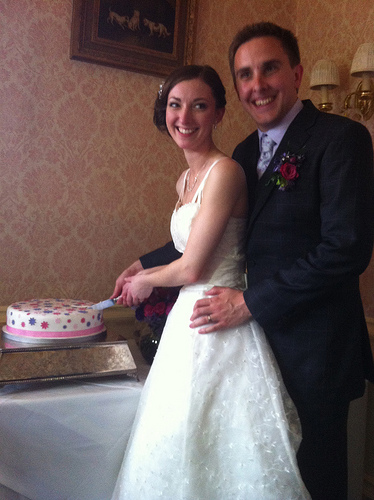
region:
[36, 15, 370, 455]
The couple look very happy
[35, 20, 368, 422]
This is a wedding photo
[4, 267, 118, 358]
The wedding cake is not very big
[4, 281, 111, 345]
The wedding cake has colored stars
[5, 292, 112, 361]
The wedding cake has white frosting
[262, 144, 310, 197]
The man has a rose in his button hole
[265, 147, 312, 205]
The rose is a red one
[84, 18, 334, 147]
The couple is smiling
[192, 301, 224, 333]
Man is wearing his wedding band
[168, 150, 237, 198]
The bride is wearing a necklace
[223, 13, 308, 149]
The man is smiling.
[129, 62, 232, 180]
The woman is smiling.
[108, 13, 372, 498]
The man is standing behind the woman.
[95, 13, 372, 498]
The man is wearing a ring on his left hand.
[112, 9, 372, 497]
The woman is wearing a wedding dress.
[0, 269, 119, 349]
The cake is pink, white and purple.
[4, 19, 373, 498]
The couple are posing.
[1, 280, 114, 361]
The cake is round.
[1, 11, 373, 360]
The couple are cutting the cake.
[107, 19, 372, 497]
The man is wearing a suit.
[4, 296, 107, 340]
frosted cake with pink and purple decorations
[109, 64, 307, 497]
woman wearing a white dress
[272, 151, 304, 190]
floral boutonniere on the man's jacket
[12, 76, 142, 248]
patterned wallpaper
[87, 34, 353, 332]
man and woman cutting a cake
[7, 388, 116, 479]
white tablecloth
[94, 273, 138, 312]
man and woman holding a knife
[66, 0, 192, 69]
framed artwork on the wall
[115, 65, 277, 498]
woman wearing a necklace and a wedding dress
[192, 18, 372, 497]
man wearing a suit and tie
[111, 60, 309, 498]
Woman wearing a white dress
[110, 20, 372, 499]
Man wearing a suit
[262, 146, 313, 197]
Roses on man's shirt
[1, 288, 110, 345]
Cake on a tray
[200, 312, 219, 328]
Ring on man's finger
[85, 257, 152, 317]
Knife in woman and man's hand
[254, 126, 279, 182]
Tie around man's neck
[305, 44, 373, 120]
Lamp on the wall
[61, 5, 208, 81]
Picture hanging on the wall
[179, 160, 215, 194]
Necklace on woman's neck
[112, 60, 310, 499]
a bride in a wedding dress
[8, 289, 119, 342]
a cake being cut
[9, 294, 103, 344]
a muli-colored cake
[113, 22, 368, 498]
a bride and a groom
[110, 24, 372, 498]
a married couple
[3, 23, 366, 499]
a wedding reception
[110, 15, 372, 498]
a man and woman smiling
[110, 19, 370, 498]
a couple standing together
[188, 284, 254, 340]
a hand with a wedding ring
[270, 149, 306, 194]
a corsage with a rose